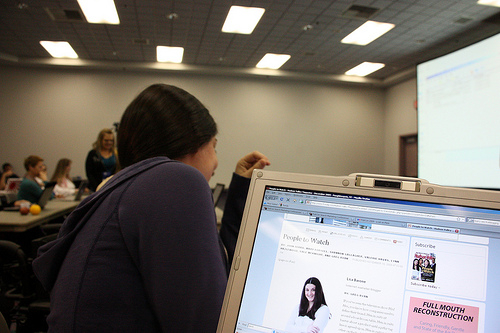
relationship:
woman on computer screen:
[289, 268, 331, 315] [234, 169, 486, 328]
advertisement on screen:
[404, 295, 481, 330] [232, 185, 498, 332]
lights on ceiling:
[39, 0, 395, 77] [0, 0, 500, 85]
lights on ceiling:
[39, 0, 395, 77] [5, 2, 483, 89]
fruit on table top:
[20, 200, 42, 215] [2, 178, 97, 229]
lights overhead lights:
[345, 58, 386, 78] [341, 20, 388, 47]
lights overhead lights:
[345, 58, 386, 78] [258, 52, 288, 71]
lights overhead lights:
[345, 58, 386, 78] [219, 5, 261, 36]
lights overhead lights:
[345, 58, 386, 78] [156, 43, 185, 63]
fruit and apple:
[21, 200, 52, 224] [30, 204, 41, 215]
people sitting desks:
[4, 77, 273, 322] [3, 174, 88, 229]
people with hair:
[29, 83, 269, 333] [97, 132, 186, 181]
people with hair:
[29, 83, 269, 333] [121, 88, 182, 124]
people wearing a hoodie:
[29, 83, 269, 333] [30, 155, 230, 331]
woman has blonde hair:
[82, 122, 126, 195] [92, 122, 111, 145]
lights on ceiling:
[39, 0, 395, 77] [21, 0, 461, 93]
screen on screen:
[232, 185, 498, 332] [232, 185, 498, 332]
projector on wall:
[417, 30, 499, 199] [382, 29, 492, 179]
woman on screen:
[287, 277, 332, 333] [198, 160, 473, 331]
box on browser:
[312, 200, 419, 217] [268, 189, 308, 209]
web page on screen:
[238, 180, 479, 331] [232, 185, 498, 332]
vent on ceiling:
[346, 0, 380, 21] [5, 2, 483, 89]